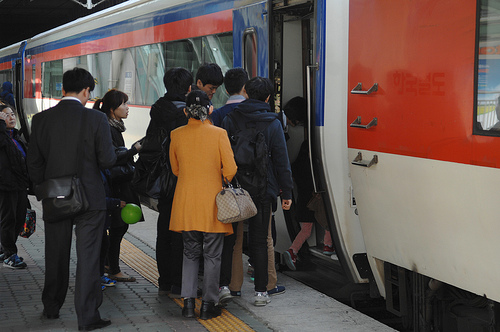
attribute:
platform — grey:
[6, 200, 401, 329]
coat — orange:
[164, 116, 235, 237]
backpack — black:
[224, 111, 274, 191]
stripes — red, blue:
[3, 6, 248, 65]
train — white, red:
[3, 1, 484, 322]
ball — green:
[119, 201, 140, 226]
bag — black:
[34, 170, 87, 227]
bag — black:
[228, 122, 272, 187]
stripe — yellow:
[114, 231, 252, 330]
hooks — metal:
[348, 79, 381, 175]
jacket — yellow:
[164, 118, 237, 240]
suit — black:
[29, 91, 117, 326]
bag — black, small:
[44, 174, 81, 218]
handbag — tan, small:
[212, 186, 262, 230]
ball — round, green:
[119, 201, 145, 227]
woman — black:
[85, 84, 145, 288]